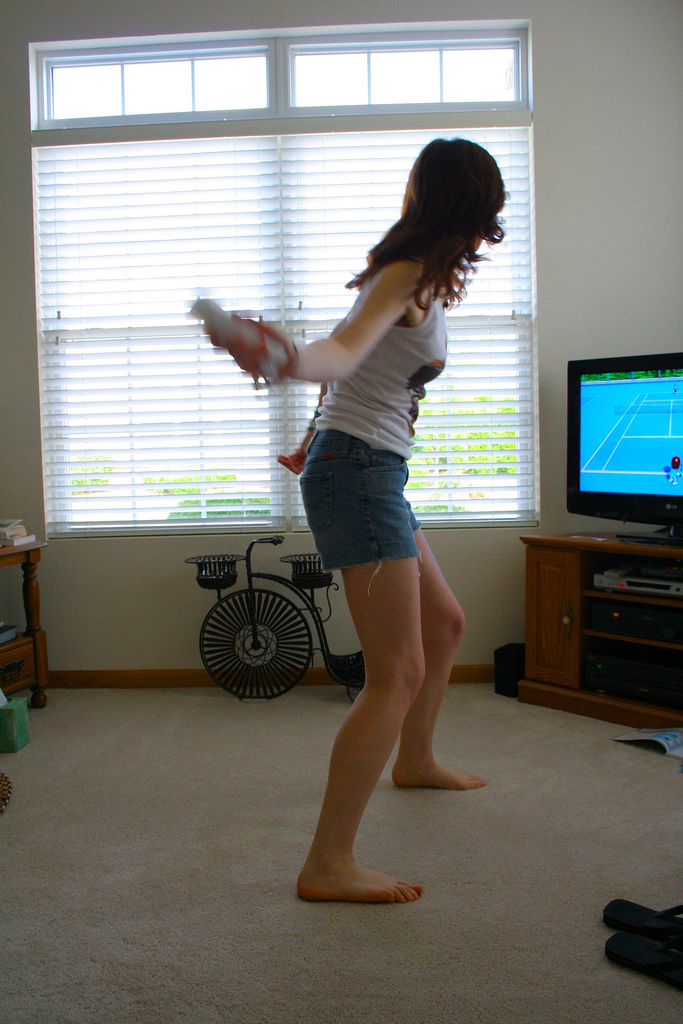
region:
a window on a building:
[39, 59, 130, 105]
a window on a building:
[191, 46, 270, 114]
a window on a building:
[440, 47, 519, 107]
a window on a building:
[39, 146, 295, 499]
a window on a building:
[287, 134, 524, 522]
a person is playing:
[171, 138, 504, 909]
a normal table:
[7, 528, 54, 717]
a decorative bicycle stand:
[180, 520, 417, 728]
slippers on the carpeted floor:
[578, 863, 680, 1005]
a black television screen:
[551, 346, 681, 557]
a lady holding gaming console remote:
[167, 111, 465, 411]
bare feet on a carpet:
[271, 727, 511, 945]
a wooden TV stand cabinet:
[508, 338, 674, 732]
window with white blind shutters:
[24, 121, 283, 555]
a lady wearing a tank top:
[301, 123, 508, 531]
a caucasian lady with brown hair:
[349, 122, 526, 380]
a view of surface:
[153, 863, 234, 932]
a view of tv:
[542, 330, 649, 507]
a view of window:
[452, 377, 570, 509]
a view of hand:
[183, 294, 277, 398]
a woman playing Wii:
[163, 118, 682, 923]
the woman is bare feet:
[180, 125, 518, 929]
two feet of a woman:
[279, 736, 501, 930]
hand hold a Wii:
[180, 285, 314, 399]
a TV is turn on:
[562, 340, 682, 536]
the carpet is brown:
[36, 700, 281, 1000]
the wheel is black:
[188, 574, 326, 714]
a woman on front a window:
[19, 22, 565, 548]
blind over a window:
[17, 17, 288, 539]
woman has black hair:
[312, 122, 532, 358]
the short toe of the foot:
[381, 890, 393, 902]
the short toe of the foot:
[392, 883, 406, 902]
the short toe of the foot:
[399, 884, 415, 903]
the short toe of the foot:
[403, 881, 415, 897]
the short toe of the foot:
[403, 876, 423, 897]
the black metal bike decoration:
[191, 528, 371, 700]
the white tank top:
[318, 282, 457, 452]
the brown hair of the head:
[353, 134, 506, 287]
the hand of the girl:
[213, 316, 295, 372]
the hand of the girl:
[276, 427, 319, 473]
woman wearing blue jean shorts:
[292, 426, 427, 570]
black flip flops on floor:
[597, 889, 681, 996]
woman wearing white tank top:
[309, 256, 456, 460]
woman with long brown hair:
[337, 135, 507, 311]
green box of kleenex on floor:
[0, 685, 31, 754]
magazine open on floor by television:
[613, 723, 682, 763]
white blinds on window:
[29, 122, 541, 550]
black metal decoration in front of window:
[184, 529, 376, 710]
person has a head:
[414, 137, 508, 261]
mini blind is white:
[43, 422, 287, 437]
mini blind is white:
[47, 508, 280, 513]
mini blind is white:
[44, 518, 273, 521]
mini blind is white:
[43, 434, 279, 441]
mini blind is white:
[46, 445, 280, 450]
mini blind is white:
[43, 388, 282, 393]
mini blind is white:
[38, 350, 238, 360]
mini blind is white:
[41, 373, 279, 386]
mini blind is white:
[421, 390, 532, 401]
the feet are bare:
[281, 750, 485, 956]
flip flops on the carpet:
[602, 876, 678, 1008]